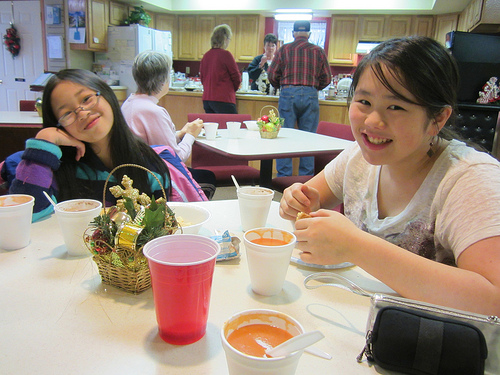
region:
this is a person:
[294, 38, 499, 328]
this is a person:
[15, 65, 191, 250]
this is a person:
[103, 42, 206, 172]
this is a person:
[185, 12, 256, 119]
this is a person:
[272, 19, 356, 182]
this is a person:
[249, 15, 292, 101]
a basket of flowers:
[74, 162, 186, 295]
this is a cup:
[210, 290, 305, 374]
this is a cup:
[144, 226, 219, 347]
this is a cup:
[227, 223, 310, 303]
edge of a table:
[277, 142, 308, 159]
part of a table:
[77, 296, 107, 334]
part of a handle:
[302, 326, 317, 355]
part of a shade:
[106, 302, 128, 331]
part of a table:
[86, 332, 116, 354]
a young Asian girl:
[240, 28, 498, 333]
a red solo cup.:
[129, 218, 233, 355]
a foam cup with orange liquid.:
[240, 206, 304, 302]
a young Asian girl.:
[11, 65, 217, 210]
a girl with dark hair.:
[334, 28, 466, 191]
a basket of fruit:
[244, 96, 289, 147]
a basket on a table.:
[79, 123, 206, 303]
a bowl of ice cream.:
[217, 294, 323, 374]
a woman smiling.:
[326, 46, 443, 171]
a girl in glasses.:
[39, 54, 144, 162]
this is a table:
[17, 312, 83, 369]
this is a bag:
[353, 305, 470, 367]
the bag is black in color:
[403, 331, 423, 343]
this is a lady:
[345, 50, 497, 259]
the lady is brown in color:
[384, 118, 418, 138]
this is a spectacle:
[54, 95, 91, 117]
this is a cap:
[293, 14, 316, 33]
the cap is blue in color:
[292, 18, 311, 30]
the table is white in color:
[53, 297, 101, 360]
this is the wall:
[336, 24, 407, 38]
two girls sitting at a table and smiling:
[2, 35, 497, 370]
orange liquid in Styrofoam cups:
[220, 226, 300, 370]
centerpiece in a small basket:
[82, 161, 175, 289]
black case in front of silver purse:
[356, 290, 498, 371]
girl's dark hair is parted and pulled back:
[346, 38, 486, 169]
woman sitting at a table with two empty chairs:
[119, 50, 354, 199]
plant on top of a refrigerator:
[106, 5, 168, 86]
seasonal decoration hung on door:
[0, 3, 26, 62]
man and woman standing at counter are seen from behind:
[174, 16, 346, 125]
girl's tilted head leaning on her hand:
[30, 68, 124, 163]